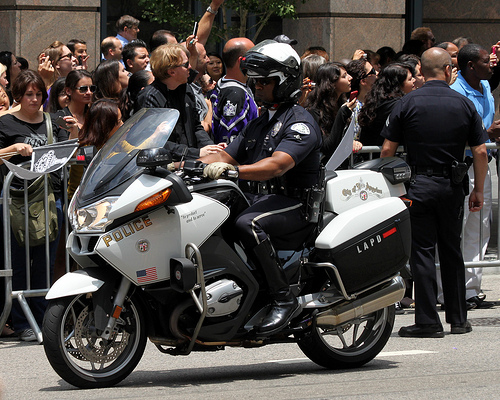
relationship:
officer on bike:
[229, 61, 311, 141] [46, 102, 414, 389]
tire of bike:
[27, 281, 153, 391] [46, 102, 414, 389]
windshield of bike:
[102, 131, 160, 164] [46, 102, 414, 389]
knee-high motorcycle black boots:
[244, 238, 308, 328] [245, 236, 305, 335]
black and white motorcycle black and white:
[240, 48, 345, 110] [240, 41, 301, 111]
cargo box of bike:
[332, 163, 405, 200] [46, 102, 414, 389]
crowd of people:
[18, 58, 170, 102] [95, 27, 286, 94]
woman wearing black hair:
[376, 61, 432, 116] [378, 81, 405, 97]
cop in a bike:
[229, 61, 311, 141] [96, 150, 340, 296]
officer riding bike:
[145, 39, 325, 335] [46, 102, 414, 389]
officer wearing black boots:
[229, 61, 311, 141] [245, 246, 293, 314]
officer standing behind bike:
[145, 39, 325, 335] [46, 102, 414, 389]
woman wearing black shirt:
[376, 61, 432, 116] [343, 86, 383, 113]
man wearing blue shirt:
[464, 46, 499, 81] [439, 71, 485, 116]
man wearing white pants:
[464, 46, 499, 81] [457, 170, 483, 251]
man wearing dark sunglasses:
[148, 43, 187, 90] [239, 79, 298, 117]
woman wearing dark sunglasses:
[73, 73, 89, 94] [77, 75, 86, 122]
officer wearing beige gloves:
[229, 61, 311, 141] [198, 93, 222, 145]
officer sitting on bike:
[145, 39, 325, 335] [46, 102, 414, 389]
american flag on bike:
[132, 265, 163, 285] [96, 150, 340, 296]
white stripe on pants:
[247, 203, 293, 228] [221, 206, 304, 266]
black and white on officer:
[240, 41, 301, 111] [145, 39, 325, 335]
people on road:
[95, 27, 286, 94] [95, 100, 172, 145]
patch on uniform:
[282, 121, 314, 140] [235, 102, 325, 221]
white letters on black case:
[345, 232, 389, 257] [346, 210, 391, 257]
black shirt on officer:
[343, 86, 383, 113] [145, 39, 325, 335]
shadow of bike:
[162, 360, 256, 378] [96, 150, 340, 296]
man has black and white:
[148, 43, 187, 90] [240, 41, 301, 111]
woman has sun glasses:
[376, 61, 432, 116] [367, 66, 381, 78]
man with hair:
[148, 43, 187, 90] [148, 43, 181, 72]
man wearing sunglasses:
[148, 43, 187, 90] [164, 57, 196, 69]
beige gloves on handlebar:
[204, 161, 235, 181] [180, 157, 239, 181]